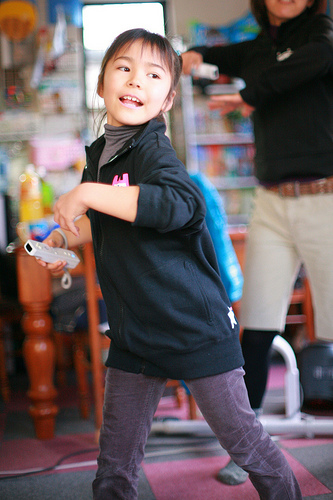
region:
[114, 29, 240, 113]
Girl has dark hair.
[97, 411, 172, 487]
Girl is wearing gray pants.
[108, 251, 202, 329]
Girl wearing dark hoodie.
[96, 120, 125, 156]
Girl wearing gray turtleneck.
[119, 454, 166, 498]
Floor is red and gray.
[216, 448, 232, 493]
Person wearing gray socks.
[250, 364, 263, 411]
Person wearing black pants.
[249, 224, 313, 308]
Person wearing tan shorts.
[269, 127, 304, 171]
Person wearing black shirt.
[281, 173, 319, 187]
Person wearing brown belt.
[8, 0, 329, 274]
woman and girl holding controllers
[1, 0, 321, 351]
the controller are white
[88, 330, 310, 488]
girl's jeans are purple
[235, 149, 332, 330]
woman's pants are khaki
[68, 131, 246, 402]
girl wearing black jacket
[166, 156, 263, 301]
girl carrying blue bag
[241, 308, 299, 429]
woman wearing black socks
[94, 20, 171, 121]
girl's hair is brown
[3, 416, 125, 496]
cord behind the girl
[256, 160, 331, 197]
woman's belt is brown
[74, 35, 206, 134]
asian girl smiling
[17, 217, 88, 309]
wii controller in a hand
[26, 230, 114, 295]
functioning wii controller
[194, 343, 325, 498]
solid purple colored jeans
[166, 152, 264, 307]
blue backpack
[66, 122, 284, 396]
solid dark colored jacket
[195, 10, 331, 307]
woman in the background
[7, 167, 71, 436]
leg of a table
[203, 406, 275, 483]
women's foot covered in a sock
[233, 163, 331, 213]
woman wearing a belt on shorts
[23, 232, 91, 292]
Girl holding remote control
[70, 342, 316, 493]
Girl wearing purple pants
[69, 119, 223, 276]
Girl wearing black sweatshirt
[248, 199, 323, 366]
Woman in white Capri pants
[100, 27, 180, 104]
Girl with black hair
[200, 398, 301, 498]
Woman standing on red mat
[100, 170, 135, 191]
Pink logo on black sweatshirt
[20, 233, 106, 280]
Girl holding Wii controller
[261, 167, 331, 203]
Woman wearing a brown belt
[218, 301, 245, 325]
Zipper on a sweatshirt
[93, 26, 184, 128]
little girl with dark hair smiling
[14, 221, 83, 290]
Wii controller with wrist strap in hand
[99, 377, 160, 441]
medium gray fabric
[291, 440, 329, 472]
light red and gray checkered carpet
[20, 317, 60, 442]
warm brown stained wood furniture leg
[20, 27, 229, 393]
young girl playing video game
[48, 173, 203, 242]
black sweatshirt with sleeve pushed up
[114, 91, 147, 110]
smile with crooked baby teeth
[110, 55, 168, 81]
girl's dark brown eyes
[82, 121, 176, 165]
girl wearing gray turtleneck under sweatshirt